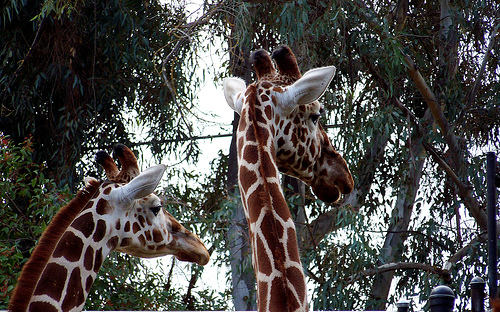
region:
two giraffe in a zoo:
[8, 33, 378, 309]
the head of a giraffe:
[213, 43, 373, 212]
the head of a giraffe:
[91, 143, 213, 267]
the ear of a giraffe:
[283, 63, 340, 112]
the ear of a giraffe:
[121, 155, 169, 196]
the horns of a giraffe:
[247, 40, 300, 77]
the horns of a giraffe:
[89, 139, 134, 179]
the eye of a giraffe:
[307, 110, 322, 130]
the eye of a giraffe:
[145, 199, 165, 217]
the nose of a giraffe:
[169, 218, 216, 271]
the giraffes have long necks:
[13, 42, 347, 310]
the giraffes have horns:
[98, 38, 300, 178]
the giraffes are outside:
[0, 0, 496, 305]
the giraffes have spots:
[6, 40, 347, 305]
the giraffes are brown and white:
[5, 40, 355, 300]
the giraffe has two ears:
[216, 60, 331, 106]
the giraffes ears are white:
[220, 62, 331, 107]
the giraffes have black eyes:
[146, 107, 316, 209]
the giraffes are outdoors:
[0, 5, 495, 305]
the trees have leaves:
[2, 0, 497, 309]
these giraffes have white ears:
[53, 45, 395, 309]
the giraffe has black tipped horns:
[249, 43, 304, 80]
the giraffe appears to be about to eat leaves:
[169, 32, 384, 306]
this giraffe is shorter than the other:
[79, 33, 339, 308]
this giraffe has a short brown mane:
[17, 165, 85, 310]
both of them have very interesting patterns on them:
[26, 205, 327, 309]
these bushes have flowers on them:
[0, 123, 58, 205]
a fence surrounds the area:
[396, 140, 495, 310]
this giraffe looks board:
[98, 133, 213, 266]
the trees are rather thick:
[25, 62, 165, 128]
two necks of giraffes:
[17, 41, 371, 310]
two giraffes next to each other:
[17, 37, 376, 310]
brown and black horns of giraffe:
[250, 43, 299, 75]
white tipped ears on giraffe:
[290, 66, 337, 98]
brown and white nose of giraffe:
[302, 150, 357, 196]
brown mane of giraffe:
[28, 202, 76, 262]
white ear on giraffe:
[98, 146, 170, 205]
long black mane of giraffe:
[250, 99, 269, 233]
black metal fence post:
[419, 268, 469, 310]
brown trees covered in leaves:
[323, 18, 448, 141]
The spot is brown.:
[68, 210, 98, 235]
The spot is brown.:
[50, 228, 87, 265]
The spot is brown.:
[26, 256, 70, 301]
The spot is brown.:
[59, 263, 88, 310]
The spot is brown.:
[82, 241, 95, 272]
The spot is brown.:
[91, 215, 108, 244]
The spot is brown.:
[237, 163, 257, 193]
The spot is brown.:
[252, 230, 274, 278]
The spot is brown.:
[266, 179, 293, 221]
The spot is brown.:
[283, 223, 302, 268]